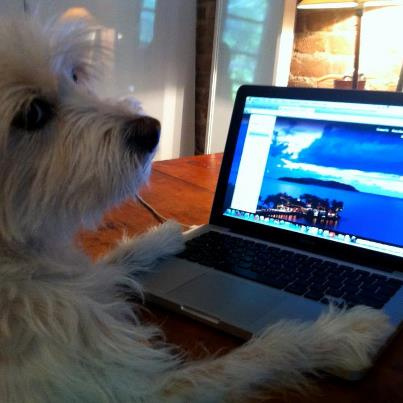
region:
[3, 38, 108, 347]
the dog is white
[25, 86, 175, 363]
the dog is white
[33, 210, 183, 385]
the dog is white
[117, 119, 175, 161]
dog's nose is black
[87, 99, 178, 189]
dog's nose is black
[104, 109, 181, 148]
dog's nose is black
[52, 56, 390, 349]
the dog is using the laptop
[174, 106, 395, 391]
laptop on the desk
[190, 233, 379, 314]
keyboard on the laptop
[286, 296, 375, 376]
dog paw on laptop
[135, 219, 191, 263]
dog paw on laptop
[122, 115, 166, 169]
nose of the dog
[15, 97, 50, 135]
eye of the dog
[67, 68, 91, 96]
eye of the dog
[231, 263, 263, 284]
keyboard on the laptop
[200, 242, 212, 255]
key on the laptop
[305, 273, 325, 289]
key on the laptop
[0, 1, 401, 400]
A dog with it's paws on a laptop.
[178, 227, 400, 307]
A laptop keyboard.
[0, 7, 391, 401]
A white dog with shade of color in its fur.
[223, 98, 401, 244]
A water scene on the laptop screen.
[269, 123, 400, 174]
Clouds in the picture on the computer.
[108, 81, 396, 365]
A black laptop.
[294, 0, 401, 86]
A lamp behind the laptop.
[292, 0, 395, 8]
The lower portion of a white lamp shade.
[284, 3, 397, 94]
A brick wall.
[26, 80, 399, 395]
A laptop on a brown wooden table.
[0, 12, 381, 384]
The dog is using the computer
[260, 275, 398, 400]
The dog's paw is white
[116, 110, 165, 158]
The nose of the dog is black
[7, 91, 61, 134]
The eye of the dog is brown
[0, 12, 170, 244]
The head of the dog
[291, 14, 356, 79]
The building is made of brick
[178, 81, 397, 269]
The top of the laptop is open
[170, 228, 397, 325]
The keyboard of the laptop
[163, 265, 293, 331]
The mouse pad is the middle of the computer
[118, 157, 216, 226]
The table is made of wood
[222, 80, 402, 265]
screen of a laptop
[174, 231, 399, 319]
black keyboard on a laptop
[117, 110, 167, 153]
black nostril on a dog's snout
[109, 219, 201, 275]
white dog paw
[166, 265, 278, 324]
mouse pad on a laptop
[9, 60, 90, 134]
brown eyes on a dog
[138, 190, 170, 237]
a black cord on a laptop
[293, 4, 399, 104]
brick wall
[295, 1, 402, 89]
a lap on the wall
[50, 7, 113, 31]
reflection of a lamp on the wall